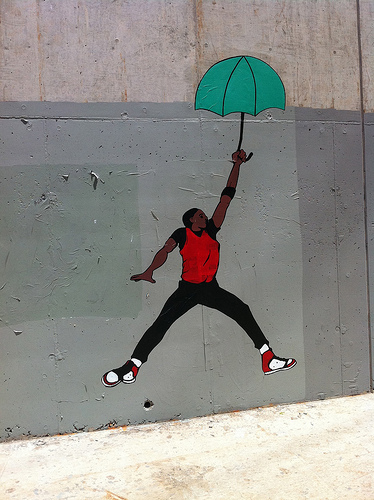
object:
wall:
[1, 1, 373, 413]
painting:
[102, 54, 297, 387]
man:
[100, 148, 296, 388]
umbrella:
[194, 56, 286, 163]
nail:
[90, 169, 100, 182]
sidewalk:
[2, 392, 374, 500]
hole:
[142, 399, 154, 410]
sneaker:
[260, 347, 295, 375]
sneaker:
[100, 359, 139, 388]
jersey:
[179, 227, 219, 285]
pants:
[131, 276, 271, 363]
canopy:
[192, 56, 286, 116]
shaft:
[236, 111, 252, 163]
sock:
[257, 343, 270, 355]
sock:
[129, 357, 143, 367]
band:
[220, 185, 236, 197]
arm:
[210, 151, 246, 237]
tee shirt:
[170, 218, 221, 250]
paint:
[1, 102, 373, 445]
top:
[0, 1, 373, 109]